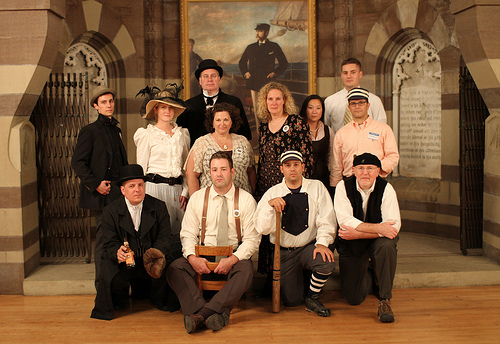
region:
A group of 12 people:
[67, 56, 431, 326]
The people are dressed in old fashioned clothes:
[74, 50, 405, 320]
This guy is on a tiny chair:
[170, 150, 260, 325]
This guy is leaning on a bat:
[258, 152, 339, 324]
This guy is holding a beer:
[89, 160, 176, 315]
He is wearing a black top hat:
[113, 154, 159, 209]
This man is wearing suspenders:
[177, 178, 262, 268]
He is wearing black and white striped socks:
[301, 261, 333, 321]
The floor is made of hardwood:
[9, 292, 84, 335]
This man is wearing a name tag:
[360, 128, 387, 143]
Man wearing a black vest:
[330, 154, 412, 327]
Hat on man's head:
[341, 150, 385, 170]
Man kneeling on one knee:
[255, 148, 348, 320]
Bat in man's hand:
[268, 195, 290, 315]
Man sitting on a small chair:
[167, 150, 262, 335]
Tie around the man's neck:
[208, 191, 237, 263]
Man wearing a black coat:
[84, 165, 184, 325]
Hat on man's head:
[113, 161, 152, 188]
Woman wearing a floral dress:
[245, 83, 319, 188]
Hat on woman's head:
[140, 81, 184, 120]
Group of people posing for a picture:
[72, 49, 429, 325]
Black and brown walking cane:
[254, 178, 289, 328]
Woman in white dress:
[125, 82, 203, 228]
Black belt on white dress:
[141, 166, 196, 191]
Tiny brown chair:
[193, 240, 247, 311]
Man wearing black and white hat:
[332, 85, 399, 202]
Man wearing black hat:
[330, 146, 429, 331]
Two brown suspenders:
[197, 178, 253, 253]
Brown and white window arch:
[374, 22, 454, 207]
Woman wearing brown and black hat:
[123, 76, 200, 231]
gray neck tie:
[216, 196, 233, 246]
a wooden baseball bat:
[273, 203, 281, 313]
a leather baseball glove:
[141, 245, 164, 275]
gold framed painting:
[178, 1, 315, 104]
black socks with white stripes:
[309, 268, 326, 299]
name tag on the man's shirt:
[366, 131, 380, 140]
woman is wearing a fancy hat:
[141, 86, 183, 121]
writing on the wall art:
[397, 84, 440, 161]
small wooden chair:
[193, 242, 233, 286]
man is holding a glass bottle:
[115, 237, 135, 265]